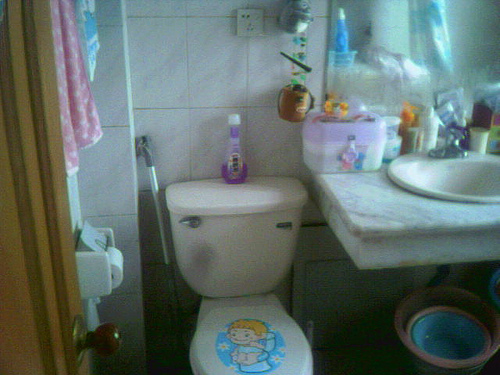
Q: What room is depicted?
A: A bathroom.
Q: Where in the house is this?
A: Bathroom.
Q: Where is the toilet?
A: By the sink.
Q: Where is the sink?
A: Below the mirror.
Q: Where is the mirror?
A: On the wall.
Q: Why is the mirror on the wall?
A: Reflections.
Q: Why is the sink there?
A: To wash hands.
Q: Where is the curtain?
A: By the bath.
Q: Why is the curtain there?
A: To keep things dry.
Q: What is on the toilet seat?
A: A small child.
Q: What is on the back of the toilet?
A: A potporri item.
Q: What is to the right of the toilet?
A: The sink.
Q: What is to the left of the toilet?
A: The toilet paper roll.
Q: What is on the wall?
A: The mirror.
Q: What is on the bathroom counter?
A: The white sink.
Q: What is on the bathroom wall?
A: The mirror.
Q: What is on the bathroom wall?
A: The white tiles.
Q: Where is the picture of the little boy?
A: Toilet.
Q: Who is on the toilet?
A: Nobody.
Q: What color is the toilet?
A: White.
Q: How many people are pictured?
A: 0.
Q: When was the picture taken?
A: Morning.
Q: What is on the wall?
A: Mirror.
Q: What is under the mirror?
A: Sink.